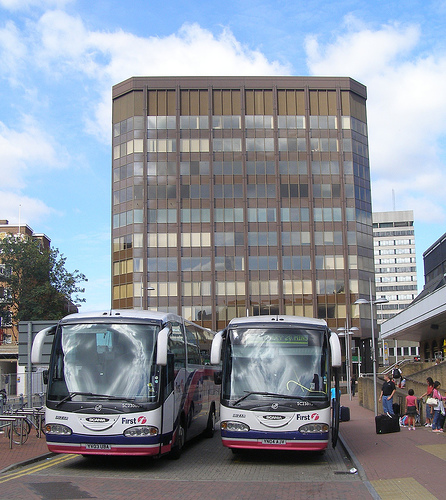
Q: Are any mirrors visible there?
A: Yes, there is a mirror.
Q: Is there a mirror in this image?
A: Yes, there is a mirror.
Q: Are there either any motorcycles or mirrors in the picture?
A: Yes, there is a mirror.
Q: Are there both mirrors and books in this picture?
A: No, there is a mirror but no books.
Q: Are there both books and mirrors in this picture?
A: No, there is a mirror but no books.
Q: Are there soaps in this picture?
A: No, there are no soaps.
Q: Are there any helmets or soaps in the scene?
A: No, there are no soaps or helmets.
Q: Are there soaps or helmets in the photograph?
A: No, there are no soaps or helmets.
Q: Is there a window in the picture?
A: Yes, there are windows.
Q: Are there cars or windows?
A: Yes, there are windows.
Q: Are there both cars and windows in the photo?
A: No, there are windows but no cars.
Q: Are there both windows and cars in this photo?
A: No, there are windows but no cars.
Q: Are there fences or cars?
A: No, there are no cars or fences.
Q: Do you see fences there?
A: No, there are no fences.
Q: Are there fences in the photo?
A: No, there are no fences.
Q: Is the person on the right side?
A: Yes, the person is on the right of the image.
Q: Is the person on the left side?
A: No, the person is on the right of the image.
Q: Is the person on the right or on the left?
A: The person is on the right of the image.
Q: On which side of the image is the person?
A: The person is on the right of the image.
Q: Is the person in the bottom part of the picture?
A: Yes, the person is in the bottom of the image.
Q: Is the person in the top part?
A: No, the person is in the bottom of the image.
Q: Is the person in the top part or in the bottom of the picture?
A: The person is in the bottom of the image.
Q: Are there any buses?
A: Yes, there is a bus.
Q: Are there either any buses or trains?
A: Yes, there is a bus.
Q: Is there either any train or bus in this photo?
A: Yes, there is a bus.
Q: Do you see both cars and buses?
A: No, there is a bus but no cars.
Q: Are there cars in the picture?
A: No, there are no cars.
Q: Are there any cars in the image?
A: No, there are no cars.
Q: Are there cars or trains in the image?
A: No, there are no cars or trains.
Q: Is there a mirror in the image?
A: Yes, there is a mirror.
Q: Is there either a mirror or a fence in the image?
A: Yes, there is a mirror.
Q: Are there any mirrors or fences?
A: Yes, there is a mirror.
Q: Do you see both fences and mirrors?
A: No, there is a mirror but no fences.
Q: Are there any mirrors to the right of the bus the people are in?
A: Yes, there is a mirror to the right of the bus.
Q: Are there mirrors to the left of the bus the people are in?
A: No, the mirror is to the right of the bus.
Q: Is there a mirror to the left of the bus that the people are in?
A: No, the mirror is to the right of the bus.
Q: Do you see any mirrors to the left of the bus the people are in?
A: No, the mirror is to the right of the bus.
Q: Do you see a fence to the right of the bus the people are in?
A: No, there is a mirror to the right of the bus.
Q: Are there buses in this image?
A: Yes, there is a bus.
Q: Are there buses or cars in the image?
A: Yes, there is a bus.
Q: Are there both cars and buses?
A: No, there is a bus but no cars.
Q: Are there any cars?
A: No, there are no cars.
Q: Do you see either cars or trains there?
A: No, there are no cars or trains.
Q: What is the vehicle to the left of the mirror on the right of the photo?
A: The vehicle is a bus.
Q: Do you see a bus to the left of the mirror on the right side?
A: Yes, there is a bus to the left of the mirror.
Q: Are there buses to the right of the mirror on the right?
A: No, the bus is to the left of the mirror.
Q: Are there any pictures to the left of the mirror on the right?
A: No, there is a bus to the left of the mirror.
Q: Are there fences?
A: No, there are no fences.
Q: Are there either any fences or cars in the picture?
A: No, there are no fences or cars.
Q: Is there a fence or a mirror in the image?
A: Yes, there is a mirror.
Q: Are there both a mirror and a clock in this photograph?
A: No, there is a mirror but no clocks.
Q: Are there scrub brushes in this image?
A: No, there are no scrub brushes.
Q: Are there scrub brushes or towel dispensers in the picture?
A: No, there are no scrub brushes or towel dispensers.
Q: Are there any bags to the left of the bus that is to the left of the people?
A: No, there is a mirror to the left of the bus.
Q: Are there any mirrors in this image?
A: Yes, there is a mirror.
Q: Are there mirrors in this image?
A: Yes, there is a mirror.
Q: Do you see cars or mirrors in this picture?
A: Yes, there is a mirror.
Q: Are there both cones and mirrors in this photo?
A: No, there is a mirror but no cones.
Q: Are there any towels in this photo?
A: No, there are no towels.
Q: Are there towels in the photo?
A: No, there are no towels.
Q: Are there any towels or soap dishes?
A: No, there are no towels or soap dishes.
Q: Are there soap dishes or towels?
A: No, there are no towels or soap dishes.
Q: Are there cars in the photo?
A: No, there are no cars.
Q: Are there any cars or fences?
A: No, there are no cars or fences.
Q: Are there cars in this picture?
A: No, there are no cars.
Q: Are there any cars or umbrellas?
A: No, there are no cars or umbrellas.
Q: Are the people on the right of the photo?
A: Yes, the people are on the right of the image.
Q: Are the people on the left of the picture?
A: No, the people are on the right of the image.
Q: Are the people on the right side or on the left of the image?
A: The people are on the right of the image.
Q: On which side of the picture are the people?
A: The people are on the right of the image.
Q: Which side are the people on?
A: The people are on the right of the image.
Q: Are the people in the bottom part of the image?
A: Yes, the people are in the bottom of the image.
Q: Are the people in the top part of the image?
A: No, the people are in the bottom of the image.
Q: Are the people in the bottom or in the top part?
A: The people are in the bottom of the image.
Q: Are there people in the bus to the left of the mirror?
A: Yes, there are people in the bus.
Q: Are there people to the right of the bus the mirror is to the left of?
A: Yes, there are people to the right of the bus.